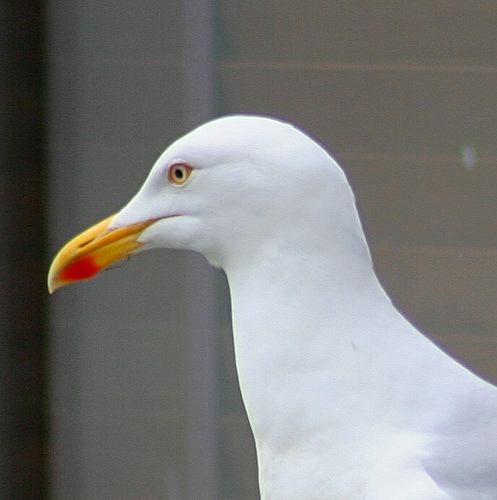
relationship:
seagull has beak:
[41, 112, 493, 500] [50, 233, 118, 288]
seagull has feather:
[41, 112, 493, 500] [387, 458, 397, 471]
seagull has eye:
[41, 112, 493, 500] [165, 159, 201, 186]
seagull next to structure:
[41, 112, 493, 500] [30, 10, 495, 109]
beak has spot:
[50, 233, 118, 288] [58, 264, 97, 282]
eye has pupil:
[165, 159, 201, 186] [178, 171, 181, 174]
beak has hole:
[50, 233, 118, 288] [77, 241, 99, 249]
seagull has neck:
[41, 112, 493, 500] [232, 249, 364, 302]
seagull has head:
[41, 112, 493, 500] [170, 118, 351, 248]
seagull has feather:
[41, 112, 493, 500] [278, 483, 295, 495]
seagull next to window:
[41, 112, 493, 500] [30, 10, 495, 109]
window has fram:
[30, 10, 495, 109] [184, 17, 217, 106]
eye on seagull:
[165, 159, 201, 186] [41, 112, 493, 500]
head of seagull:
[170, 118, 351, 248] [41, 112, 493, 500]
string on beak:
[115, 255, 131, 272] [50, 233, 118, 288]